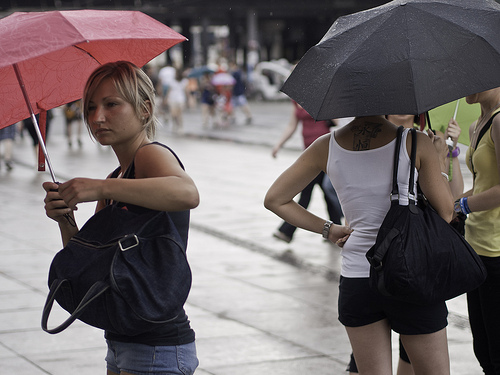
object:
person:
[40, 59, 201, 375]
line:
[223, 315, 339, 361]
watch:
[323, 220, 333, 239]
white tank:
[326, 128, 418, 278]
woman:
[263, 115, 453, 375]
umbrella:
[0, 8, 188, 227]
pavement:
[0, 113, 488, 375]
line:
[267, 289, 330, 309]